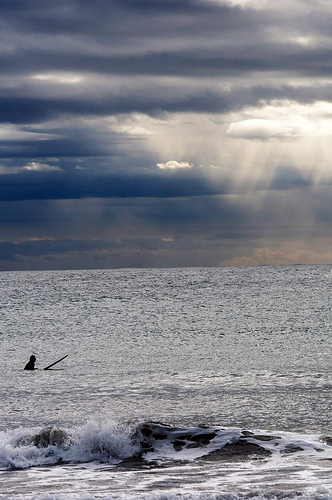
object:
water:
[0, 265, 331, 499]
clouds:
[0, 1, 331, 272]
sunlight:
[0, 1, 331, 271]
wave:
[1, 417, 331, 474]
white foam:
[262, 430, 331, 496]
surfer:
[23, 354, 37, 372]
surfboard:
[43, 354, 68, 372]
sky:
[0, 1, 331, 272]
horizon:
[0, 263, 331, 272]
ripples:
[0, 265, 331, 498]